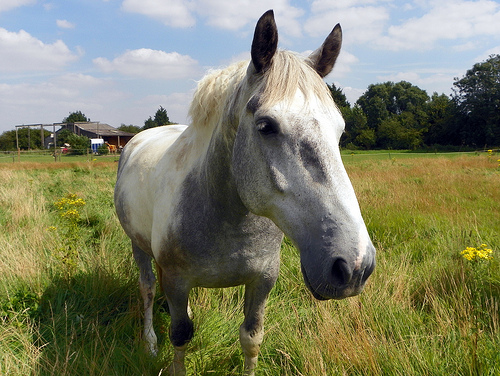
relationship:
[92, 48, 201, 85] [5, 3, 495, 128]
cloud in sky